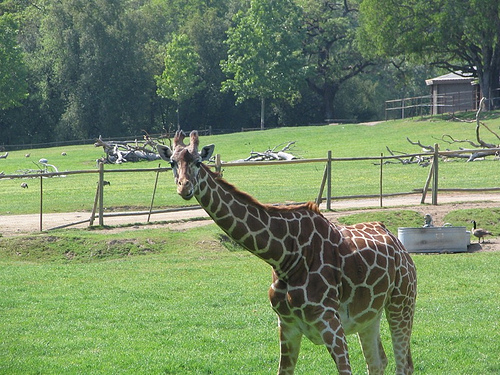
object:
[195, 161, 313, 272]
neck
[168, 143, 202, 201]
head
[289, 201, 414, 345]
body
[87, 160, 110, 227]
wood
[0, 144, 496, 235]
fence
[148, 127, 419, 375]
giraffe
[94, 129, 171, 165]
branches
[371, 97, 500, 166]
trunk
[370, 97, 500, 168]
branches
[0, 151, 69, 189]
birds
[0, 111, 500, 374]
grass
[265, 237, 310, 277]
wrinkles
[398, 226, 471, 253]
metal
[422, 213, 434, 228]
birds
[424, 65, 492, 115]
building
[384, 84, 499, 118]
fence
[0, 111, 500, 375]
field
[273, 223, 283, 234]
brown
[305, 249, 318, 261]
brown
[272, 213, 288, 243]
brown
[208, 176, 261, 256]
spot